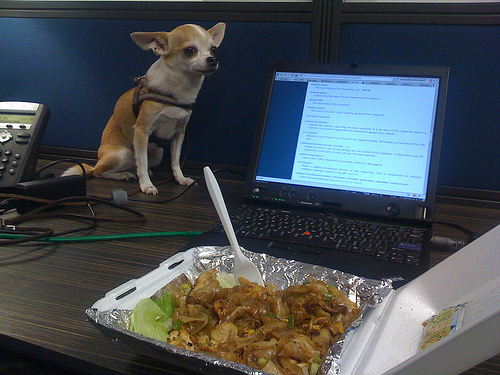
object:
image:
[253, 69, 441, 201]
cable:
[0, 192, 149, 246]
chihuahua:
[57, 21, 227, 197]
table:
[0, 156, 499, 373]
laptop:
[177, 60, 449, 291]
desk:
[1, 150, 500, 375]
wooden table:
[1, 150, 498, 374]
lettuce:
[128, 287, 177, 343]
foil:
[123, 269, 361, 375]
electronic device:
[0, 97, 49, 191]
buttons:
[209, 203, 427, 267]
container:
[80, 225, 499, 375]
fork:
[201, 166, 263, 289]